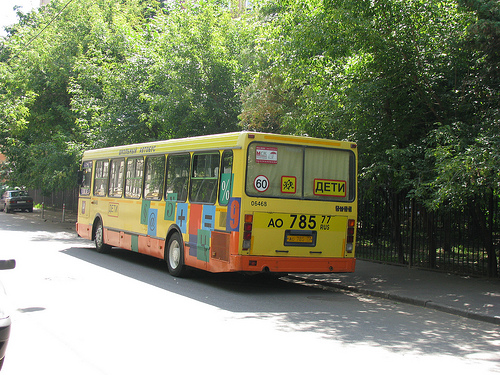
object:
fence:
[354, 185, 500, 280]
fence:
[28, 176, 79, 214]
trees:
[356, 119, 499, 277]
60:
[256, 179, 268, 189]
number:
[321, 215, 326, 223]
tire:
[166, 231, 197, 277]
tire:
[94, 220, 112, 255]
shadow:
[58, 247, 368, 313]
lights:
[244, 214, 254, 223]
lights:
[347, 218, 355, 227]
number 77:
[321, 215, 331, 224]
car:
[1, 190, 34, 213]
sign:
[313, 177, 346, 197]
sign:
[175, 202, 188, 234]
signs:
[147, 208, 157, 237]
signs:
[140, 199, 151, 225]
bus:
[74, 130, 359, 278]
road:
[0, 212, 499, 375]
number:
[290, 214, 298, 228]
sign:
[255, 145, 278, 164]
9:
[229, 199, 239, 229]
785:
[290, 214, 317, 229]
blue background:
[226, 197, 241, 232]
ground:
[0, 207, 498, 375]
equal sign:
[201, 205, 216, 232]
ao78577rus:
[267, 214, 331, 231]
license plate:
[287, 235, 313, 243]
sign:
[253, 174, 270, 192]